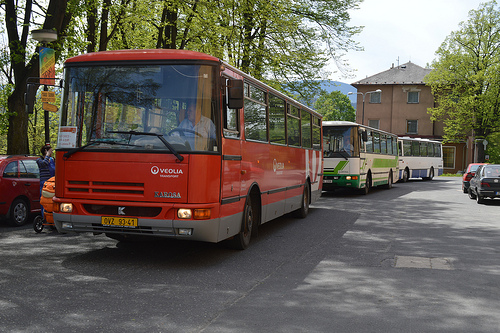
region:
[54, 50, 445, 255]
The buses are lined up.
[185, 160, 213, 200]
The bus is red.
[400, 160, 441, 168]
The bus is white.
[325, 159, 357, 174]
The bus is green and white.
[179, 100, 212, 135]
A driver is in the bus.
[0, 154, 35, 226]
A red car is parked on the street.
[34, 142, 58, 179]
A person is next to the car.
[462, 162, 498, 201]
Two cars are parked on the street.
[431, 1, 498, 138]
A tree is in the background.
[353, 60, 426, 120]
A building is behind the buses.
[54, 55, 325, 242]
an orange passenger bus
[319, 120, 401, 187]
a white bus with green stripes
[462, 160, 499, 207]
two cars parked on the street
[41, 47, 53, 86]
a rainbow flag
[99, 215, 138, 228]
a yellow license plate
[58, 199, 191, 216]
the headlights are on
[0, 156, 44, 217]
a red car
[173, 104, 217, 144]
the driver is in the bus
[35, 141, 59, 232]
a man standing on the street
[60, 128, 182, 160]
windshield wipers on the bus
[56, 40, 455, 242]
Three buses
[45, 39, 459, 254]
The buses are driving on the road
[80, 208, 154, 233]
License plate OVZ 9341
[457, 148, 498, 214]
Cars parked on the side of the street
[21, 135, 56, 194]
Woman walking near the red bus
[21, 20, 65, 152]
A streetlight that isn't turned on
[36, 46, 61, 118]
Several signs on the street light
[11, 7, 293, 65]
Trees along the side of the street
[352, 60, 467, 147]
A brown house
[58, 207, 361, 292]
shadow of a bus on the road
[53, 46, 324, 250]
red and white passenger bus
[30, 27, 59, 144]
light on top of black metal pole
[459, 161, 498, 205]
two compact cars are parked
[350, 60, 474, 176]
three story brick building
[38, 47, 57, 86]
colorful sign hanging on a post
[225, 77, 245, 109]
rectangular shaped rear view mirror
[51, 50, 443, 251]
three buses lined up on the road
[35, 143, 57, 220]
woman is covering her eyes with her right hand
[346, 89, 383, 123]
two street lights on one pole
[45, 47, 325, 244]
a red and white bus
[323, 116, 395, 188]
a green and white bus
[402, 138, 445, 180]
a purple and white bus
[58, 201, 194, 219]
head lights on a bus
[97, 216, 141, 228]
a yellow tag on a bus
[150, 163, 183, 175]
white letters on a bus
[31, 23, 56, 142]
a light on a pole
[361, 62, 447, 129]
a brown brick building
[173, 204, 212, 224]
Lights on a bus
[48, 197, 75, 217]
Lights on a bus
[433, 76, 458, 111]
green leaves on the tree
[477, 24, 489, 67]
green leaves on the tree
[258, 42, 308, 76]
green leaves on the tree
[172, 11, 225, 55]
green leaves on the tree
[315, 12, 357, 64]
green leaves on the treegreen leaves on the tree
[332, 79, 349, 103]
green leaves on the tree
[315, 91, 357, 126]
green leaves on the tree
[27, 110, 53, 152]
green leaves on the tree